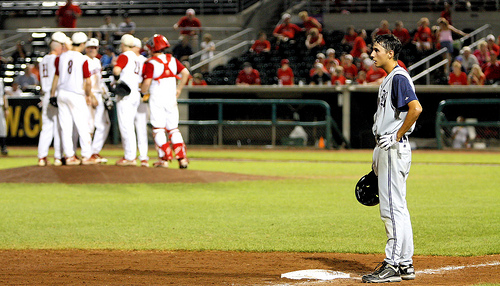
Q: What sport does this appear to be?
A: Baseball.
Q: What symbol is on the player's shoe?
A: Check mark.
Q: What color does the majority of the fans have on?
A: Red.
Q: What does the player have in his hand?
A: Helmet.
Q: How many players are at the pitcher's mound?
A: 7.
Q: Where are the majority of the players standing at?
A: Pitcher's Mound.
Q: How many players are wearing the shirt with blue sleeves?
A: One.